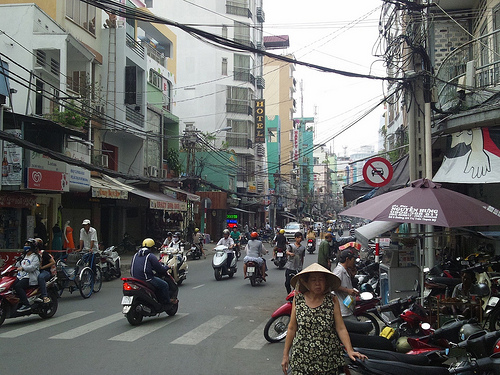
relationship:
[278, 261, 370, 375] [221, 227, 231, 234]
people wears helmet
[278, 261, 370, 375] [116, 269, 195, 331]
people on motorcycle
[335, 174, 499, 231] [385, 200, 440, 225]
umbrella with letters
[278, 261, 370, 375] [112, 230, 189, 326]
people on motorcycle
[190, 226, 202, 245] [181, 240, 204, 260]
person on motorcycle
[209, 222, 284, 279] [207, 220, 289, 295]
person on motorcycle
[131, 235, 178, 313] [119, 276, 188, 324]
man is on motorcycle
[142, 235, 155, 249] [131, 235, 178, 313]
helmet is on man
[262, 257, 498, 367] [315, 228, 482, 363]
motorcycles parked in large group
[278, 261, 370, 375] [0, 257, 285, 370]
people on street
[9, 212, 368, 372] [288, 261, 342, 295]
people wears hat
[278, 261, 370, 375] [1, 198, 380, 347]
people have great time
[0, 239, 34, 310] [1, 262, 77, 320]
person on motorcycle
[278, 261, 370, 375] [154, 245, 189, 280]
people on motorcycle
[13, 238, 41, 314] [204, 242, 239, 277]
person on motorcycle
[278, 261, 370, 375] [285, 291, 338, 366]
people in dress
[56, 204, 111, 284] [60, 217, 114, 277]
mannequin wearing dress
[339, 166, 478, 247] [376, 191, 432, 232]
umbrella with white text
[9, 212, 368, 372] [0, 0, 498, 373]
people out in city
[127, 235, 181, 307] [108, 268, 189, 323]
man on motorcycle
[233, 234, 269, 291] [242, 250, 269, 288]
person on motorcycle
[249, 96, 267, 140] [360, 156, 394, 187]
hotel written on round sign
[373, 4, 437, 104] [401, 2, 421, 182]
tangle on pole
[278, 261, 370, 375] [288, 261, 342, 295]
people wearing hat